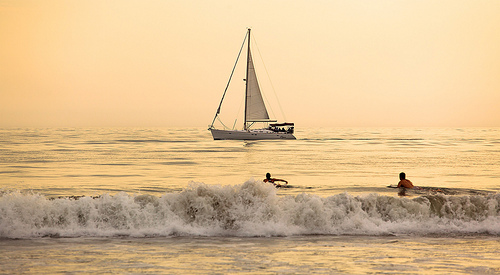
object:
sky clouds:
[20, 16, 181, 116]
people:
[261, 171, 289, 193]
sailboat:
[203, 27, 302, 144]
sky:
[1, 5, 498, 135]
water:
[2, 126, 498, 273]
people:
[387, 170, 445, 193]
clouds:
[30, 11, 172, 131]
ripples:
[2, 125, 496, 269]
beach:
[10, 220, 477, 267]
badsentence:
[293, 211, 332, 241]